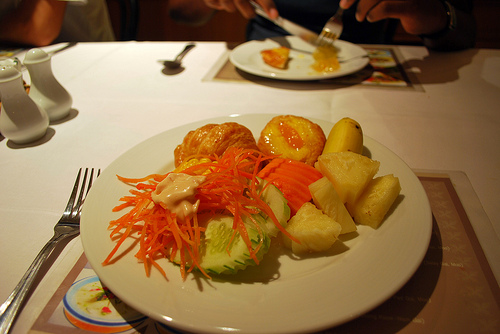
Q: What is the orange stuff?
A: Carrots.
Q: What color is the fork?
A: Silver.